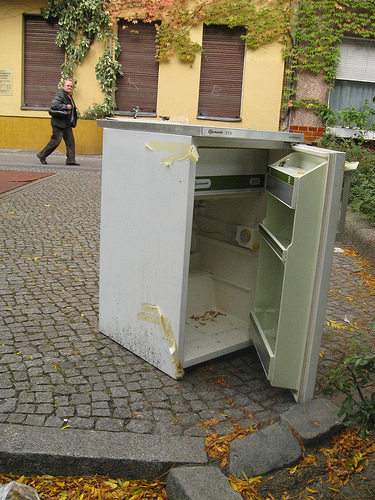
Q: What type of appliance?
A: Refrigerator.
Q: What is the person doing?
A: Walking.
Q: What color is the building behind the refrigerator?
A: Yellow.